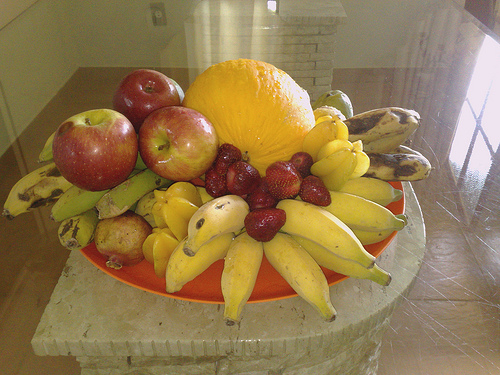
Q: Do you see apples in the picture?
A: Yes, there is an apple.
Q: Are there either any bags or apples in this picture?
A: Yes, there is an apple.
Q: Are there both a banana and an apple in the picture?
A: Yes, there are both an apple and a banana.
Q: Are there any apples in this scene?
A: Yes, there is an apple.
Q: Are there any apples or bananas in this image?
A: Yes, there is an apple.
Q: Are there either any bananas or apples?
A: Yes, there is an apple.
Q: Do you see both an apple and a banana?
A: Yes, there are both an apple and a banana.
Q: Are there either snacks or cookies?
A: No, there are no snacks or cookies.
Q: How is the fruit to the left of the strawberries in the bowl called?
A: The fruit is an apple.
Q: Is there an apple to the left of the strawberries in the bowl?
A: Yes, there is an apple to the left of the strawberries.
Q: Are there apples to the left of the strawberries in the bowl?
A: Yes, there is an apple to the left of the strawberries.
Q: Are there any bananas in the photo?
A: Yes, there is a banana.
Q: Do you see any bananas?
A: Yes, there is a banana.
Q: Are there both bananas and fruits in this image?
A: Yes, there are both a banana and a fruit.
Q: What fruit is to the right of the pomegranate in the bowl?
A: The fruit is a banana.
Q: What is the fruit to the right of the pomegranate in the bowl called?
A: The fruit is a banana.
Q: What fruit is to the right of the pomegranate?
A: The fruit is a banana.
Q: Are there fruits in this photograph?
A: Yes, there is a fruit.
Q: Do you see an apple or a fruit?
A: Yes, there is a fruit.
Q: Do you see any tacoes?
A: No, there are no tacoes.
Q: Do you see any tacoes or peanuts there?
A: No, there are no tacoes or peanuts.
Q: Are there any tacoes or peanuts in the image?
A: No, there are no tacoes or peanuts.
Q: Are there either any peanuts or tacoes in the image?
A: No, there are no tacoes or peanuts.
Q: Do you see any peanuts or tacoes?
A: No, there are no tacoes or peanuts.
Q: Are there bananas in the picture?
A: Yes, there is a banana.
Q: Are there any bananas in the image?
A: Yes, there is a banana.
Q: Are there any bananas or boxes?
A: Yes, there is a banana.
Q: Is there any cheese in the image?
A: No, there is no cheese.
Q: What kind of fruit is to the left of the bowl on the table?
A: The fruit is a banana.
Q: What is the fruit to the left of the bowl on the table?
A: The fruit is a banana.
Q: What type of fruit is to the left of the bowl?
A: The fruit is a banana.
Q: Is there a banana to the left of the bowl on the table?
A: Yes, there is a banana to the left of the bowl.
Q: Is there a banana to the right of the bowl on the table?
A: No, the banana is to the left of the bowl.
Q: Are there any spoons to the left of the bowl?
A: No, there is a banana to the left of the bowl.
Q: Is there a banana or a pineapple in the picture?
A: Yes, there are bananas.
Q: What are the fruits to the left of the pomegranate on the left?
A: The fruits are bananas.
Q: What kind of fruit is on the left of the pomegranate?
A: The fruits are bananas.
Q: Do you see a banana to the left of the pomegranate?
A: Yes, there are bananas to the left of the pomegranate.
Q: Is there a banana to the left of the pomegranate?
A: Yes, there are bananas to the left of the pomegranate.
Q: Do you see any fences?
A: No, there are no fences.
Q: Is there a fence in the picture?
A: No, there are no fences.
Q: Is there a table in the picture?
A: Yes, there is a table.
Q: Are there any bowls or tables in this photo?
A: Yes, there is a table.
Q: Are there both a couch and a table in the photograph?
A: No, there is a table but no couches.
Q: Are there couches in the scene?
A: No, there are no couches.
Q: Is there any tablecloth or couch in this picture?
A: No, there are no couches or tablecloths.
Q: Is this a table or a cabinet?
A: This is a table.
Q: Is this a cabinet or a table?
A: This is a table.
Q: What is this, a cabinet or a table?
A: This is a table.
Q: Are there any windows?
A: Yes, there are windows.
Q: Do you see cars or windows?
A: Yes, there are windows.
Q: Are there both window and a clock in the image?
A: No, there are windows but no clocks.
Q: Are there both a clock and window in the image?
A: No, there are windows but no clocks.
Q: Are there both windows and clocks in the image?
A: No, there are windows but no clocks.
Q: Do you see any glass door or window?
A: Yes, there are glass windows.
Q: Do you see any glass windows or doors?
A: Yes, there are glass windows.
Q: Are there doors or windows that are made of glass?
A: Yes, the windows are made of glass.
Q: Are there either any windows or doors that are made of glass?
A: Yes, the windows are made of glass.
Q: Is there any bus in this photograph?
A: No, there are no buses.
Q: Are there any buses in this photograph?
A: No, there are no buses.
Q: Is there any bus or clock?
A: No, there are no buses or clocks.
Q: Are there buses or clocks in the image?
A: No, there are no buses or clocks.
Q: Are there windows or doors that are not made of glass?
A: No, there are windows but they are made of glass.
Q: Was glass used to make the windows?
A: Yes, the windows are made of glass.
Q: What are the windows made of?
A: The windows are made of glass.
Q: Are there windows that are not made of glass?
A: No, there are windows but they are made of glass.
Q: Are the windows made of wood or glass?
A: The windows are made of glass.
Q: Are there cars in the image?
A: No, there are no cars.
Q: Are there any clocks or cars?
A: No, there are no cars or clocks.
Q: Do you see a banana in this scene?
A: Yes, there are bananas.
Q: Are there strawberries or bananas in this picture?
A: Yes, there are bananas.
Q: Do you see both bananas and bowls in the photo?
A: Yes, there are both bananas and a bowl.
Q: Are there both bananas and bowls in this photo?
A: Yes, there are both bananas and a bowl.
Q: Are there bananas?
A: Yes, there are bananas.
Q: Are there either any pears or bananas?
A: Yes, there are bananas.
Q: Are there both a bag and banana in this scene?
A: No, there are bananas but no bags.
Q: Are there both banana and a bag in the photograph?
A: No, there are bananas but no bags.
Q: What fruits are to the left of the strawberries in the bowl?
A: The fruits are bananas.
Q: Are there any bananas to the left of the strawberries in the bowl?
A: Yes, there are bananas to the left of the strawberries.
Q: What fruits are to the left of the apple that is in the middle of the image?
A: The fruits are bananas.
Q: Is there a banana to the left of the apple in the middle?
A: Yes, there are bananas to the left of the apple.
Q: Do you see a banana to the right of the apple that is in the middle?
A: No, the bananas are to the left of the apple.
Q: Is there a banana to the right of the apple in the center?
A: No, the bananas are to the left of the apple.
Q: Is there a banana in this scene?
A: Yes, there are bananas.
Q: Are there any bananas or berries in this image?
A: Yes, there are bananas.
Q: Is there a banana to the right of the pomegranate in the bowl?
A: Yes, there are bananas to the right of the pomegranate.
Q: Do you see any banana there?
A: Yes, there are bananas.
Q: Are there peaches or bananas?
A: Yes, there are bananas.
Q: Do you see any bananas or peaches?
A: Yes, there are bananas.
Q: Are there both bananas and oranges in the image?
A: Yes, there are both bananas and oranges.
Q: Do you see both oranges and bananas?
A: Yes, there are both bananas and oranges.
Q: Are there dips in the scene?
A: No, there are no dips.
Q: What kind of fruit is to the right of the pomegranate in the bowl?
A: The fruits are bananas.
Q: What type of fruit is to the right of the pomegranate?
A: The fruits are bananas.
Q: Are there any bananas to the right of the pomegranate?
A: Yes, there are bananas to the right of the pomegranate.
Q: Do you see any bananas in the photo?
A: Yes, there are bananas.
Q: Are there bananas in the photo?
A: Yes, there are bananas.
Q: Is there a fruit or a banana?
A: Yes, there are bananas.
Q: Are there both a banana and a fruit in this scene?
A: Yes, there are both a banana and a fruit.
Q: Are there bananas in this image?
A: Yes, there are bananas.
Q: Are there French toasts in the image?
A: No, there are no French toasts.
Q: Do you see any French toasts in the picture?
A: No, there are no French toasts.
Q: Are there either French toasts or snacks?
A: No, there are no French toasts or snacks.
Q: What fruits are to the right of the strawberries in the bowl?
A: The fruits are bananas.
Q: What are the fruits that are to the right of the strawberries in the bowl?
A: The fruits are bananas.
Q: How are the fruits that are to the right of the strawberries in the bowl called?
A: The fruits are bananas.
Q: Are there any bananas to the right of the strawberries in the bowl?
A: Yes, there are bananas to the right of the strawberries.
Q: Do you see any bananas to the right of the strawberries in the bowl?
A: Yes, there are bananas to the right of the strawberries.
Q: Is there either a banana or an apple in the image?
A: Yes, there are bananas.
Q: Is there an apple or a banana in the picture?
A: Yes, there are bananas.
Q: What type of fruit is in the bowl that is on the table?
A: The fruits are bananas.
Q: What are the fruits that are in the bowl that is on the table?
A: The fruits are bananas.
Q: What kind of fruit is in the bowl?
A: The fruits are bananas.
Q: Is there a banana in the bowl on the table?
A: Yes, there are bananas in the bowl.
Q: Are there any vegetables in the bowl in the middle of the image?
A: No, there are bananas in the bowl.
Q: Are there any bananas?
A: Yes, there are bananas.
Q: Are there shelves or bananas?
A: Yes, there are bananas.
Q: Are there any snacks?
A: No, there are no snacks.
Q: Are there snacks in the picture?
A: No, there are no snacks.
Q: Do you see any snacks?
A: No, there are no snacks.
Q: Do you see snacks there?
A: No, there are no snacks.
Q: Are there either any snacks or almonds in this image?
A: No, there are no snacks or almonds.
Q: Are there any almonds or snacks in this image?
A: No, there are no snacks or almonds.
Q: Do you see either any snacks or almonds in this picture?
A: No, there are no snacks or almonds.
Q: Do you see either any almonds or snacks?
A: No, there are no snacks or almonds.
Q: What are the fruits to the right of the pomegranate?
A: The fruits are bananas.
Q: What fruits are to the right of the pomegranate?
A: The fruits are bananas.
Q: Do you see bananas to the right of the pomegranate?
A: Yes, there are bananas to the right of the pomegranate.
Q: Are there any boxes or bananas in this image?
A: Yes, there are bananas.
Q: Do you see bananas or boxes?
A: Yes, there are bananas.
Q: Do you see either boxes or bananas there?
A: Yes, there are bananas.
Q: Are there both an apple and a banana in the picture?
A: Yes, there are both a banana and an apple.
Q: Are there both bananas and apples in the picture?
A: Yes, there are both bananas and apples.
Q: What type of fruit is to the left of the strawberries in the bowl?
A: The fruits are bananas.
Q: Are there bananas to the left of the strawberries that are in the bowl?
A: Yes, there are bananas to the left of the strawberries.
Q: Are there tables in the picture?
A: Yes, there is a table.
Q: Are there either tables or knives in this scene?
A: Yes, there is a table.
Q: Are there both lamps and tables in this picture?
A: No, there is a table but no lamps.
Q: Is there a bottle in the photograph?
A: No, there are no bottles.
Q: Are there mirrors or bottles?
A: No, there are no bottles or mirrors.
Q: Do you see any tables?
A: Yes, there is a table.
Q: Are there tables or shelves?
A: Yes, there is a table.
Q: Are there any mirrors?
A: No, there are no mirrors.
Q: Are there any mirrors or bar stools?
A: No, there are no mirrors or bar stools.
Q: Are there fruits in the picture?
A: Yes, there is a fruit.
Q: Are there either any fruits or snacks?
A: Yes, there is a fruit.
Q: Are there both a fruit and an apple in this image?
A: Yes, there are both a fruit and an apple.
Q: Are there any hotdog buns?
A: No, there are no hotdog buns.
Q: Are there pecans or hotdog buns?
A: No, there are no hotdog buns or pecans.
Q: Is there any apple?
A: Yes, there is an apple.